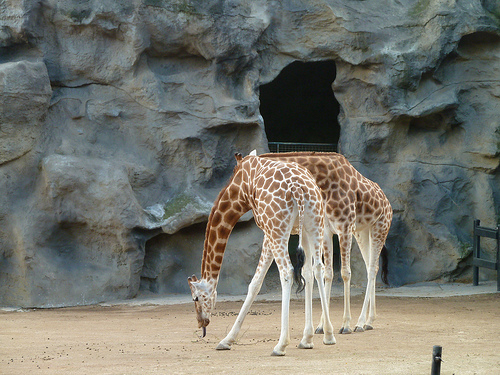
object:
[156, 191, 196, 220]
green moss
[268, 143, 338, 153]
fence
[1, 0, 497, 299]
cliffs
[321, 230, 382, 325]
legs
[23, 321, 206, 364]
sandy consistency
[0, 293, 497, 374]
floor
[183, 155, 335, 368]
giraffe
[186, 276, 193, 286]
ears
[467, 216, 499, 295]
fence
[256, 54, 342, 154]
big hole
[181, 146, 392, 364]
two giraffes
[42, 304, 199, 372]
field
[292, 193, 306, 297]
tail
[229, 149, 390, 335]
giraffe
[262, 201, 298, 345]
tall legs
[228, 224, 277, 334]
tall legs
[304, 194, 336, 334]
tall legs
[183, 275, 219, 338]
head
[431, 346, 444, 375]
pole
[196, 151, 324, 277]
spots